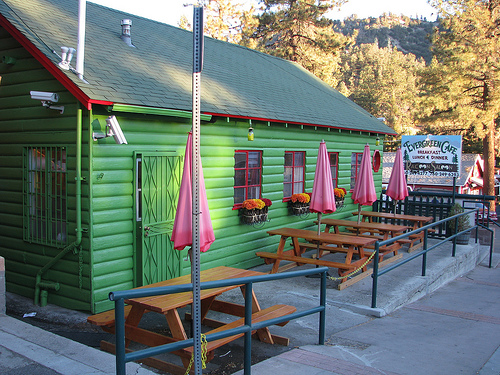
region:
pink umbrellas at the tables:
[160, 135, 420, 250]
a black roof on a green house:
[2, 0, 405, 177]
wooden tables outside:
[97, 187, 435, 372]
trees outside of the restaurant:
[195, 0, 497, 169]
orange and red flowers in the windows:
[222, 178, 357, 236]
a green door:
[135, 148, 195, 315]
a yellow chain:
[186, 326, 211, 372]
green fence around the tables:
[100, 190, 497, 373]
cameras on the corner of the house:
[28, 86, 128, 150]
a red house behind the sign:
[381, 148, 491, 198]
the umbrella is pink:
[311, 135, 341, 220]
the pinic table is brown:
[281, 232, 351, 267]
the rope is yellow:
[188, 326, 216, 368]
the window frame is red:
[228, 143, 275, 204]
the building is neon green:
[204, 142, 229, 184]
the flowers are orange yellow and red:
[236, 192, 278, 214]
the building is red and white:
[469, 173, 484, 192]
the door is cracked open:
[127, 141, 155, 274]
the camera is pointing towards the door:
[91, 105, 138, 159]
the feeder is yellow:
[243, 122, 260, 144]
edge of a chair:
[198, 297, 218, 314]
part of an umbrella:
[205, 225, 215, 248]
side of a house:
[94, 235, 97, 286]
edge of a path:
[455, 252, 457, 272]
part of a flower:
[264, 211, 287, 234]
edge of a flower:
[254, 209, 260, 214]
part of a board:
[331, 222, 347, 257]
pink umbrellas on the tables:
[170, 126, 417, 247]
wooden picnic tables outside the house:
[95, 191, 424, 366]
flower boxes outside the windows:
[236, 187, 357, 224]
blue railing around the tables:
[112, 200, 493, 374]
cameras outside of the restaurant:
[28, 85, 135, 152]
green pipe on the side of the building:
[26, 105, 85, 312]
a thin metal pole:
[180, 4, 207, 374]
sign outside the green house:
[398, 128, 465, 191]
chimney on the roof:
[114, 15, 138, 56]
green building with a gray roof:
[4, 0, 410, 320]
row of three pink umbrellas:
[304, 138, 424, 224]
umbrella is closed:
[160, 131, 225, 289]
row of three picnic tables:
[257, 203, 439, 293]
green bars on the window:
[17, 146, 77, 251]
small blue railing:
[100, 265, 342, 374]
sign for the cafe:
[394, 128, 469, 187]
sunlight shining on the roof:
[169, 61, 226, 102]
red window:
[229, 149, 274, 209]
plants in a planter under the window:
[232, 193, 279, 225]